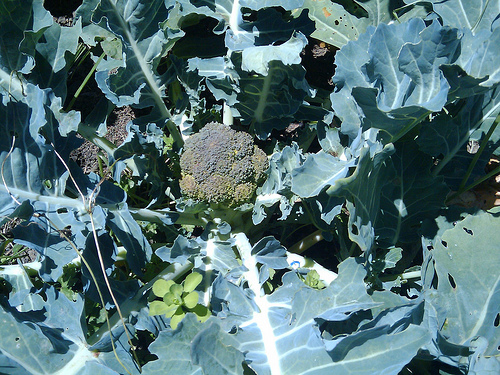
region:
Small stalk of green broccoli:
[175, 119, 270, 206]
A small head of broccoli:
[175, 123, 270, 209]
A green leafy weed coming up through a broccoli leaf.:
[147, 272, 211, 327]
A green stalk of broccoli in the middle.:
[179, 121, 269, 209]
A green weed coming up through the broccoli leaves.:
[146, 272, 212, 327]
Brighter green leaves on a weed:
[149, 275, 209, 326]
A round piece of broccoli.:
[178, 126, 270, 205]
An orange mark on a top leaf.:
[322, 7, 332, 17]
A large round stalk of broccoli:
[176, 122, 269, 209]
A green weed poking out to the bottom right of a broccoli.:
[302, 268, 324, 290]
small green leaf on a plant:
[179, 266, 206, 296]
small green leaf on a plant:
[182, 289, 203, 309]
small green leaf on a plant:
[191, 302, 215, 319]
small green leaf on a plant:
[167, 306, 184, 331]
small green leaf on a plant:
[167, 281, 184, 297]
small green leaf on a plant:
[150, 277, 170, 298]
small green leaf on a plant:
[145, 297, 167, 319]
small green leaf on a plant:
[161, 291, 176, 306]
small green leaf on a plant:
[163, 303, 178, 319]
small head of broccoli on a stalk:
[165, 112, 275, 219]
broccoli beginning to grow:
[167, 120, 270, 210]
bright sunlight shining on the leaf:
[242, 292, 294, 347]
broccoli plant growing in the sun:
[0, 19, 498, 371]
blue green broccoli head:
[173, 119, 267, 209]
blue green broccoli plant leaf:
[316, 19, 463, 166]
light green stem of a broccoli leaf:
[281, 249, 333, 283]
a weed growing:
[156, 271, 207, 325]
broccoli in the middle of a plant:
[167, 114, 274, 222]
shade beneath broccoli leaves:
[300, 35, 343, 95]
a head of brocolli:
[178, 118, 263, 208]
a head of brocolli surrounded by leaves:
[0, 2, 496, 372]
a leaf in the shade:
[350, 143, 447, 278]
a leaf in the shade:
[218, 73, 307, 138]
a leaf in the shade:
[1, 0, 35, 77]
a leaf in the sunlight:
[140, 229, 430, 374]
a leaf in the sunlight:
[2, 283, 134, 373]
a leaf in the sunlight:
[405, 204, 498, 374]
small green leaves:
[145, 272, 212, 332]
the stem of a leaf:
[127, 208, 201, 228]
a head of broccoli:
[178, 120, 278, 215]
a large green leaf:
[199, 215, 420, 373]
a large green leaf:
[6, 249, 146, 365]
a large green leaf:
[154, 278, 221, 332]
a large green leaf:
[420, 208, 497, 363]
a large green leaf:
[254, 50, 439, 239]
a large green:
[3, 130, 190, 250]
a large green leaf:
[14, 1, 159, 124]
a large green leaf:
[166, 6, 266, 125]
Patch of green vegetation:
[21, 11, 174, 188]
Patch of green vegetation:
[358, 69, 462, 176]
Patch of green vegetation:
[305, 260, 438, 347]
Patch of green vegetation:
[31, 139, 199, 302]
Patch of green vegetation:
[221, 68, 414, 217]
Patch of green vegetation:
[253, 83, 424, 236]